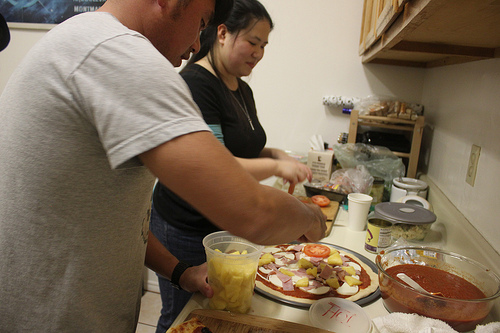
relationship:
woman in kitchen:
[150, 0, 316, 329] [4, 0, 499, 328]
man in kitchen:
[5, 1, 341, 328] [4, 0, 499, 328]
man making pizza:
[5, 1, 341, 328] [248, 237, 383, 303]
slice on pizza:
[305, 243, 328, 258] [248, 237, 383, 303]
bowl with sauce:
[375, 241, 499, 324] [386, 263, 487, 316]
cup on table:
[343, 192, 375, 231] [170, 148, 499, 331]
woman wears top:
[150, 0, 316, 329] [153, 60, 269, 230]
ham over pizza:
[262, 255, 354, 291] [248, 237, 383, 303]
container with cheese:
[201, 231, 262, 314] [208, 246, 255, 309]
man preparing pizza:
[5, 1, 341, 328] [248, 237, 383, 303]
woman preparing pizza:
[150, 0, 316, 329] [248, 237, 383, 303]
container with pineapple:
[204, 232, 263, 316] [209, 248, 253, 307]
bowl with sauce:
[375, 241, 499, 324] [386, 264, 485, 297]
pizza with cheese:
[248, 237, 383, 303] [266, 246, 365, 296]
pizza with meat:
[248, 237, 383, 303] [263, 237, 363, 296]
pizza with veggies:
[248, 237, 383, 303] [267, 235, 357, 298]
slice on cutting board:
[312, 194, 330, 206] [292, 194, 340, 234]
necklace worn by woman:
[204, 53, 253, 129] [150, 0, 316, 329]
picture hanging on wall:
[1, 0, 102, 39] [6, 1, 441, 288]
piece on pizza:
[297, 276, 310, 289] [248, 237, 383, 303]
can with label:
[364, 216, 396, 254] [367, 224, 392, 251]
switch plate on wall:
[462, 142, 482, 186] [6, 1, 441, 288]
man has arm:
[0, 1, 326, 327] [89, 26, 328, 245]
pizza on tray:
[248, 237, 383, 303] [251, 234, 384, 309]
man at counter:
[5, 1, 341, 328] [168, 153, 500, 331]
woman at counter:
[150, 0, 316, 329] [168, 153, 500, 331]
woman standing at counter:
[150, 0, 316, 329] [168, 153, 500, 331]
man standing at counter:
[5, 1, 341, 328] [168, 153, 500, 331]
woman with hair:
[150, 0, 316, 329] [180, 0, 275, 78]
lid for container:
[308, 296, 373, 331] [204, 232, 263, 316]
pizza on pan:
[248, 237, 383, 303] [247, 236, 386, 307]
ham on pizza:
[262, 255, 354, 291] [248, 237, 383, 303]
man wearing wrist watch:
[5, 1, 341, 328] [170, 261, 190, 285]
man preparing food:
[5, 1, 341, 328] [246, 178, 384, 306]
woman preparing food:
[150, 0, 316, 329] [246, 178, 384, 306]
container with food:
[204, 232, 263, 316] [207, 248, 260, 315]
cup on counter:
[343, 192, 375, 231] [168, 153, 500, 331]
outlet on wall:
[464, 142, 487, 190] [412, 57, 498, 274]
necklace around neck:
[204, 53, 253, 129] [198, 54, 257, 93]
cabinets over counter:
[356, 1, 500, 75] [168, 153, 500, 331]